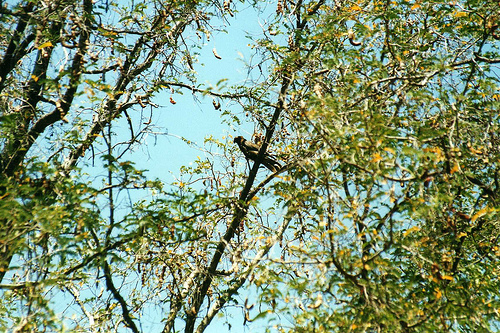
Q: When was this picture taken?
A: During the day.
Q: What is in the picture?
A: Trees and a bird.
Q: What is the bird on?
A: A branch.